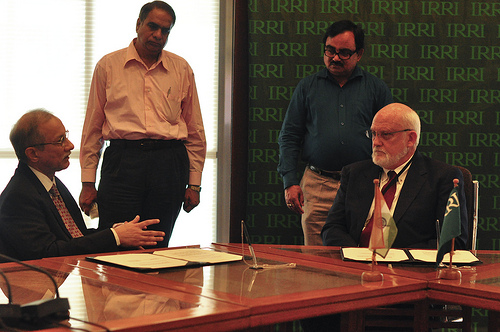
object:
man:
[0, 108, 165, 258]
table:
[0, 242, 499, 330]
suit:
[0, 162, 121, 258]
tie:
[47, 184, 84, 239]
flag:
[369, 177, 400, 259]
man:
[78, 0, 207, 248]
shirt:
[78, 38, 207, 186]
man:
[277, 21, 393, 250]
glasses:
[324, 49, 357, 60]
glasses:
[364, 129, 413, 139]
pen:
[167, 87, 171, 98]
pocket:
[160, 93, 182, 124]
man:
[321, 102, 472, 245]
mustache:
[329, 61, 344, 66]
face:
[324, 39, 358, 73]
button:
[340, 105, 344, 108]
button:
[340, 121, 345, 126]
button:
[341, 141, 345, 145]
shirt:
[277, 65, 393, 189]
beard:
[371, 145, 408, 167]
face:
[371, 115, 408, 163]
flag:
[435, 186, 461, 269]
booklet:
[83, 248, 257, 272]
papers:
[93, 253, 188, 268]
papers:
[154, 247, 244, 262]